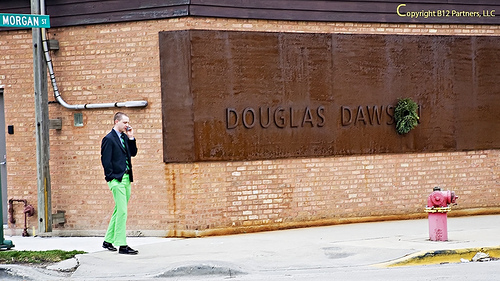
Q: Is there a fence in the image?
A: No, there are no fences.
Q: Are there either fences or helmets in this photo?
A: No, there are no fences or helmets.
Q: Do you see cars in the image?
A: No, there are no cars.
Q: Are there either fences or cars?
A: No, there are no cars or fences.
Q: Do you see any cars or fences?
A: No, there are no cars or fences.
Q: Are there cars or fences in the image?
A: No, there are no cars or fences.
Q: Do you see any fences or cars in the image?
A: No, there are no cars or fences.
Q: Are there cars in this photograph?
A: No, there are no cars.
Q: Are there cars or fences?
A: No, there are no cars or fences.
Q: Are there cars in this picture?
A: No, there are no cars.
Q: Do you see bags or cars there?
A: No, there are no cars or bags.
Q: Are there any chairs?
A: No, there are no chairs.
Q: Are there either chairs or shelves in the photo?
A: No, there are no chairs or shelves.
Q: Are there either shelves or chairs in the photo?
A: No, there are no chairs or shelves.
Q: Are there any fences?
A: No, there are no fences.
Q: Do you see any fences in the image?
A: No, there are no fences.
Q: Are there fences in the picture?
A: No, there are no fences.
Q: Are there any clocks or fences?
A: No, there are no fences or clocks.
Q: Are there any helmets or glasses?
A: No, there are no glasses or helmets.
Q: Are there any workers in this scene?
A: No, there are no workers.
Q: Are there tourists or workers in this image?
A: No, there are no workers or tourists.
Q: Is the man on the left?
A: Yes, the man is on the left of the image.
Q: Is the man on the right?
A: No, the man is on the left of the image.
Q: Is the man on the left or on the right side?
A: The man is on the left of the image.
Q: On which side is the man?
A: The man is on the left of the image.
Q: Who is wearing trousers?
A: The man is wearing trousers.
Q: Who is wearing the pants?
A: The man is wearing trousers.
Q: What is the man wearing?
A: The man is wearing trousers.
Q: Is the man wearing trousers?
A: Yes, the man is wearing trousers.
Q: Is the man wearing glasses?
A: No, the man is wearing trousers.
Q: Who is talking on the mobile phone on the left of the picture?
A: The man is talking on the mobile phone.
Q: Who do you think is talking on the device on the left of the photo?
A: The man is talking on the mobile phone.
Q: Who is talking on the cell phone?
A: The man is talking on the mobile phone.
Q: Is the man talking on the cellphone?
A: Yes, the man is talking on the cellphone.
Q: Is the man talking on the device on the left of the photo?
A: Yes, the man is talking on the cellphone.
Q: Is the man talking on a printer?
A: No, the man is talking on the cellphone.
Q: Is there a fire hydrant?
A: Yes, there is a fire hydrant.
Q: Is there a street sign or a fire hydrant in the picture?
A: Yes, there is a fire hydrant.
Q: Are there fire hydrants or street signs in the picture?
A: Yes, there is a fire hydrant.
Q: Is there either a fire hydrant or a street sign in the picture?
A: Yes, there is a fire hydrant.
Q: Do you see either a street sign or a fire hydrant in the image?
A: Yes, there is a fire hydrant.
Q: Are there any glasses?
A: No, there are no glasses.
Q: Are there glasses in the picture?
A: No, there are no glasses.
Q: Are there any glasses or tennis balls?
A: No, there are no glasses or tennis balls.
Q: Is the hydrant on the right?
A: Yes, the hydrant is on the right of the image.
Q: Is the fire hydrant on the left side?
A: No, the fire hydrant is on the right of the image.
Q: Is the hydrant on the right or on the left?
A: The hydrant is on the right of the image.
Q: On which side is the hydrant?
A: The hydrant is on the right of the image.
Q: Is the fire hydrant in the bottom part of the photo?
A: Yes, the fire hydrant is in the bottom of the image.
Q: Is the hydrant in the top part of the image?
A: No, the hydrant is in the bottom of the image.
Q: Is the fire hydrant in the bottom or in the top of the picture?
A: The fire hydrant is in the bottom of the image.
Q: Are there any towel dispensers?
A: No, there are no towel dispensers.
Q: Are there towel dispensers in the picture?
A: No, there are no towel dispensers.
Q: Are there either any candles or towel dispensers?
A: No, there are no towel dispensers or candles.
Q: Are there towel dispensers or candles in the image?
A: No, there are no towel dispensers or candles.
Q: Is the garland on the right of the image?
A: Yes, the garland is on the right of the image.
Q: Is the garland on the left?
A: No, the garland is on the right of the image.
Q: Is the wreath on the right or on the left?
A: The wreath is on the right of the image.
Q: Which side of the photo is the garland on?
A: The garland is on the right of the image.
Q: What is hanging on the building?
A: The wreath is hanging on the building.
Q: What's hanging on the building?
A: The wreath is hanging on the building.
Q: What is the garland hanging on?
A: The garland is hanging on the building.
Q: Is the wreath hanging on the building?
A: Yes, the wreath is hanging on the building.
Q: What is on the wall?
A: The wreath is on the wall.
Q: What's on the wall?
A: The wreath is on the wall.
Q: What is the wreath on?
A: The wreath is on the wall.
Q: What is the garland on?
A: The wreath is on the wall.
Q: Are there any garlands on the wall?
A: Yes, there is a garland on the wall.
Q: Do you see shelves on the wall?
A: No, there is a garland on the wall.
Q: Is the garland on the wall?
A: Yes, the garland is on the wall.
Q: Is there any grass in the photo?
A: Yes, there is grass.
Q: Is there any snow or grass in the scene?
A: Yes, there is grass.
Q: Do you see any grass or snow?
A: Yes, there is grass.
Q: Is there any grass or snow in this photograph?
A: Yes, there is grass.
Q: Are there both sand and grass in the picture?
A: No, there is grass but no sand.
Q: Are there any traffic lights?
A: No, there are no traffic lights.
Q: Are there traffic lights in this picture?
A: No, there are no traffic lights.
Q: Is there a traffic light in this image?
A: No, there are no traffic lights.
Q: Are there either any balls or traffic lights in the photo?
A: No, there are no traffic lights or balls.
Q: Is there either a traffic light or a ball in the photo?
A: No, there are no traffic lights or balls.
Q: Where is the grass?
A: The grass is on the sidewalk.